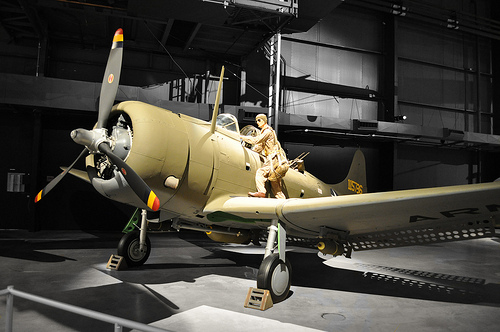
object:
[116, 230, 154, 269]
wheel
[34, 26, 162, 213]
prop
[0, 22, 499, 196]
wall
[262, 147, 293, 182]
bag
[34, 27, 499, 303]
airplane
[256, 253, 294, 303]
wheel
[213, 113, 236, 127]
windshield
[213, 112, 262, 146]
cockpit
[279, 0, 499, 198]
doors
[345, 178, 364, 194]
numbers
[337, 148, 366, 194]
fin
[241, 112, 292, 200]
man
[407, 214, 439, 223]
lettering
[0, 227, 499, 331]
floor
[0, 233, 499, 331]
shadows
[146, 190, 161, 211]
stripe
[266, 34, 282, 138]
ladder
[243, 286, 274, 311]
blocks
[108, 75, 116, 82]
writing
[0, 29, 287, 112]
railing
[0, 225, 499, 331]
platform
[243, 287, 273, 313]
wedge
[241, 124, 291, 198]
uniform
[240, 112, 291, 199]
mannequin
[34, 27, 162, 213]
propeller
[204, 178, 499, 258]
wing